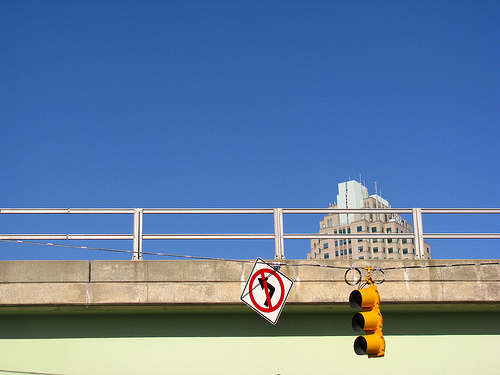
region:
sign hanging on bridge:
[233, 248, 312, 332]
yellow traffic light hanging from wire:
[335, 262, 403, 364]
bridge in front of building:
[300, 172, 431, 275]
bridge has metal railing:
[10, 200, 485, 282]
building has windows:
[300, 182, 443, 265]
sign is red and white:
[235, 255, 300, 332]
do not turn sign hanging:
[237, 253, 304, 324]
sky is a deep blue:
[87, 49, 497, 161]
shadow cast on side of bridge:
[7, 294, 497, 344]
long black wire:
[5, 232, 496, 282]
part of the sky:
[386, 45, 448, 102]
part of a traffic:
[353, 297, 381, 344]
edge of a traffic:
[371, 318, 388, 368]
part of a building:
[366, 217, 391, 231]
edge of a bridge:
[153, 299, 197, 321]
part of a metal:
[288, 197, 322, 225]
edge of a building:
[333, 177, 366, 189]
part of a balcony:
[161, 191, 226, 251]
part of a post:
[272, 225, 284, 247]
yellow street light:
[346, 265, 386, 359]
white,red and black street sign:
[240, 254, 300, 323]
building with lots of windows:
[301, 180, 431, 260]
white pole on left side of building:
[371, 178, 380, 194]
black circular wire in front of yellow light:
[342, 266, 362, 286]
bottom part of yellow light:
[355, 335, 386, 357]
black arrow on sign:
[258, 277, 276, 304]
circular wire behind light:
[369, 270, 389, 283]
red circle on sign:
[251, 266, 286, 314]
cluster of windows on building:
[330, 228, 352, 259]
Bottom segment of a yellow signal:
[351, 332, 387, 357]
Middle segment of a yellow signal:
[348, 310, 385, 332]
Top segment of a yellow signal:
[347, 287, 384, 311]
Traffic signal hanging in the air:
[348, 264, 387, 360]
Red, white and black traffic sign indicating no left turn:
[240, 258, 295, 324]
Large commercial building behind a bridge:
[305, 178, 430, 258]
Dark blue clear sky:
[1, 0, 499, 258]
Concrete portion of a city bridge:
[0, 260, 499, 315]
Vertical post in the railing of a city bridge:
[132, 206, 144, 258]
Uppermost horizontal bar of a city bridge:
[0, 206, 499, 216]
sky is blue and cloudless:
[49, 1, 404, 141]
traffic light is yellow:
[350, 287, 384, 363]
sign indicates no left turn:
[247, 253, 281, 322]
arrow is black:
[259, 270, 276, 306]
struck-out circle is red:
[250, 264, 285, 314]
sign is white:
[238, 265, 289, 323]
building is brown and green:
[297, 170, 429, 277]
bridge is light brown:
[1, 232, 487, 302]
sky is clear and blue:
[100, 0, 377, 143]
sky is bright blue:
[0, 0, 149, 176]